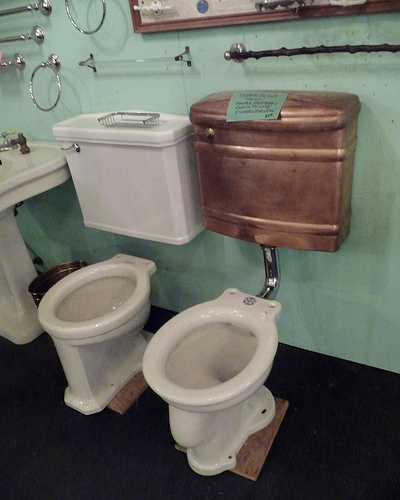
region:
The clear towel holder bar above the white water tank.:
[80, 48, 189, 73]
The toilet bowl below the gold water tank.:
[143, 287, 279, 473]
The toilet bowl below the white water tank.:
[41, 251, 147, 411]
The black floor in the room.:
[1, 326, 390, 498]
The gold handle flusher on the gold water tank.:
[186, 129, 214, 142]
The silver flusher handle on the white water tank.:
[60, 141, 83, 153]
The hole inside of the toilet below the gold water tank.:
[217, 365, 236, 380]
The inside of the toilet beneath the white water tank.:
[76, 286, 121, 318]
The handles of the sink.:
[4, 123, 31, 156]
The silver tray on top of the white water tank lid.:
[98, 105, 155, 130]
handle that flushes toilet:
[59, 141, 84, 158]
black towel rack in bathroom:
[235, 37, 397, 87]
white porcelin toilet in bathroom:
[147, 291, 280, 473]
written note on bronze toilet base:
[226, 87, 286, 122]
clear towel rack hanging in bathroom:
[87, 49, 193, 73]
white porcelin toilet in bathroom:
[43, 255, 153, 397]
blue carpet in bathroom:
[331, 374, 398, 499]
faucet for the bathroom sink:
[0, 123, 32, 158]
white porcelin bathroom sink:
[0, 125, 62, 265]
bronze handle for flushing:
[189, 126, 220, 144]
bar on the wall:
[79, 62, 199, 71]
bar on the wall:
[208, 52, 397, 59]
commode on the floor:
[143, 296, 290, 476]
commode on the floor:
[44, 272, 135, 406]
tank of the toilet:
[194, 107, 357, 248]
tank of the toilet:
[59, 119, 204, 251]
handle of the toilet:
[194, 129, 220, 149]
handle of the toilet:
[59, 141, 81, 159]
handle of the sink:
[11, 131, 48, 154]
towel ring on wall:
[14, 62, 76, 116]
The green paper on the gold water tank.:
[232, 90, 285, 120]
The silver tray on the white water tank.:
[93, 109, 161, 127]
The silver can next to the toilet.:
[19, 248, 91, 317]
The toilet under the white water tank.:
[22, 263, 146, 403]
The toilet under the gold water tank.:
[151, 282, 275, 466]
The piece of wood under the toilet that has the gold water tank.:
[169, 393, 286, 477]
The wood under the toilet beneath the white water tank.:
[96, 359, 152, 413]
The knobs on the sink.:
[5, 127, 30, 148]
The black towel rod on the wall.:
[222, 42, 399, 62]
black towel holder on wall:
[266, 41, 376, 59]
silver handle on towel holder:
[220, 43, 243, 64]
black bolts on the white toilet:
[251, 405, 271, 419]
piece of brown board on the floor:
[231, 443, 273, 479]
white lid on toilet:
[139, 307, 286, 398]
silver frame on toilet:
[240, 243, 298, 290]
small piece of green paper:
[215, 80, 300, 142]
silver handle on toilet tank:
[60, 141, 90, 160]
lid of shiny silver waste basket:
[26, 256, 88, 289]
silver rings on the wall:
[20, 49, 83, 100]